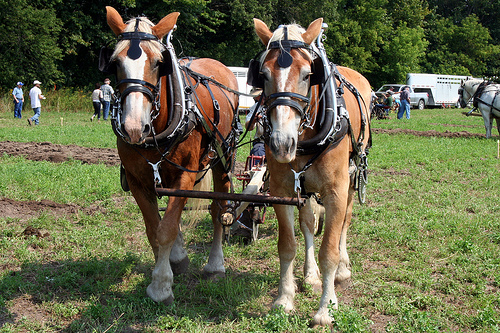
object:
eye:
[256, 66, 271, 82]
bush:
[434, 64, 475, 77]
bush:
[0, 0, 68, 90]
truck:
[373, 82, 434, 111]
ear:
[153, 10, 181, 39]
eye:
[151, 59, 165, 74]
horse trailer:
[405, 70, 481, 109]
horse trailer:
[219, 66, 263, 112]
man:
[26, 80, 51, 126]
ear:
[299, 17, 327, 46]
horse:
[244, 17, 374, 328]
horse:
[103, 5, 240, 310]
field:
[0, 107, 500, 332]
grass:
[0, 150, 139, 204]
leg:
[483, 111, 492, 135]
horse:
[455, 76, 500, 137]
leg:
[271, 171, 298, 299]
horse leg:
[317, 173, 351, 310]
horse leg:
[148, 156, 200, 290]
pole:
[152, 187, 308, 209]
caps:
[33, 79, 43, 86]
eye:
[302, 70, 314, 82]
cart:
[99, 2, 375, 328]